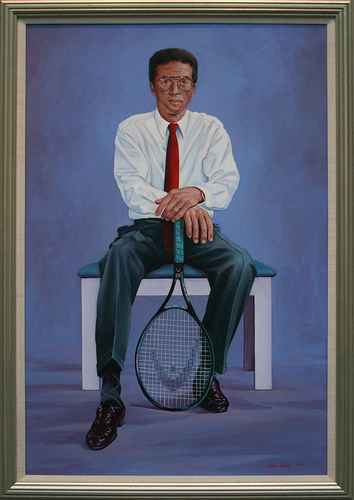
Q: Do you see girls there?
A: No, there are no girls.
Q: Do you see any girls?
A: No, there are no girls.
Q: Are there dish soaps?
A: No, there are no dish soaps.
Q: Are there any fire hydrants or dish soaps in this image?
A: No, there are no dish soaps or fire hydrants.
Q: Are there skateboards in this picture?
A: No, there are no skateboards.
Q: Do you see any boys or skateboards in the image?
A: No, there are no skateboards or boys.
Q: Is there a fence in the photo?
A: No, there are no fences.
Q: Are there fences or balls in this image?
A: No, there are no fences or balls.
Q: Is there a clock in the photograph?
A: No, there are no clocks.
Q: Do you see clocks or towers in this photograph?
A: No, there are no clocks or towers.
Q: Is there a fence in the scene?
A: No, there are no fences.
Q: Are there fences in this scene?
A: No, there are no fences.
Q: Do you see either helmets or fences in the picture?
A: No, there are no fences or helmets.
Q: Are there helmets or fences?
A: No, there are no fences or helmets.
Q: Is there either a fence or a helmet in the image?
A: No, there are no fences or helmets.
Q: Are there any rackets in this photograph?
A: Yes, there is a racket.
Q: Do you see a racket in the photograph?
A: Yes, there is a racket.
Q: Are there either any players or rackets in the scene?
A: Yes, there is a racket.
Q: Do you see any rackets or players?
A: Yes, there is a racket.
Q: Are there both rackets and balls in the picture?
A: No, there is a racket but no balls.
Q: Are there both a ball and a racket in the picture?
A: No, there is a racket but no balls.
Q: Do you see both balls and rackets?
A: No, there is a racket but no balls.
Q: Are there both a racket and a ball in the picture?
A: No, there is a racket but no balls.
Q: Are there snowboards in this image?
A: No, there are no snowboards.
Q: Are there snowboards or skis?
A: No, there are no snowboards or skis.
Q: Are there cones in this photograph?
A: No, there are no cones.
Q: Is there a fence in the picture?
A: No, there are no fences.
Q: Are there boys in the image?
A: No, there are no boys.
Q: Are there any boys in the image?
A: No, there are no boys.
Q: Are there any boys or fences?
A: No, there are no boys or fences.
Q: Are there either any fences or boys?
A: No, there are no boys or fences.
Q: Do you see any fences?
A: No, there are no fences.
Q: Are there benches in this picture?
A: Yes, there is a bench.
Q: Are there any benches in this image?
A: Yes, there is a bench.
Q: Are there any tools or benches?
A: Yes, there is a bench.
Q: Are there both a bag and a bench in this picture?
A: No, there is a bench but no bags.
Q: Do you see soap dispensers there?
A: No, there are no soap dispensers.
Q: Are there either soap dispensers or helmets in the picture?
A: No, there are no soap dispensers or helmets.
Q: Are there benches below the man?
A: Yes, there is a bench below the man.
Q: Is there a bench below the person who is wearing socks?
A: Yes, there is a bench below the man.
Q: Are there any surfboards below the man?
A: No, there is a bench below the man.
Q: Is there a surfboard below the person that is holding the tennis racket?
A: No, there is a bench below the man.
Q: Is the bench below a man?
A: Yes, the bench is below a man.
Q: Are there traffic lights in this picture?
A: No, there are no traffic lights.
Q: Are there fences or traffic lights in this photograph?
A: No, there are no traffic lights or fences.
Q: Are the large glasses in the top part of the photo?
A: Yes, the glasses are in the top of the image.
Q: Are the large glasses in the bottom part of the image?
A: No, the glasses are in the top of the image.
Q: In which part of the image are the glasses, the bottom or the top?
A: The glasses are in the top of the image.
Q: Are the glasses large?
A: Yes, the glasses are large.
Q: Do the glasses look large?
A: Yes, the glasses are large.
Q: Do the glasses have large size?
A: Yes, the glasses are large.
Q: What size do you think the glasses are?
A: The glasses are large.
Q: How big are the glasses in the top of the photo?
A: The glasses are large.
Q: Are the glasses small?
A: No, the glasses are large.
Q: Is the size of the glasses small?
A: No, the glasses are large.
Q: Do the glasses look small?
A: No, the glasses are large.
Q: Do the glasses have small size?
A: No, the glasses are large.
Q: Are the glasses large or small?
A: The glasses are large.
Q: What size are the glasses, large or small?
A: The glasses are large.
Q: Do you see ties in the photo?
A: Yes, there is a tie.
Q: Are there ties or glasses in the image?
A: Yes, there is a tie.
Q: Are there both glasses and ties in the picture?
A: Yes, there are both a tie and glasses.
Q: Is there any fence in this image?
A: No, there are no fences.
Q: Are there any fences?
A: No, there are no fences.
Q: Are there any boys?
A: No, there are no boys.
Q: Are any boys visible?
A: No, there are no boys.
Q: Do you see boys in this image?
A: No, there are no boys.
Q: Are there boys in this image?
A: No, there are no boys.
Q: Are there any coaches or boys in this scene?
A: No, there are no boys or coaches.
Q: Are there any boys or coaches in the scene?
A: No, there are no boys or coaches.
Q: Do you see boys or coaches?
A: No, there are no boys or coaches.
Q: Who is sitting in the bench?
A: The man is sitting in the bench.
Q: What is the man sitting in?
A: The man is sitting in the bench.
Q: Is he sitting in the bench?
A: Yes, the man is sitting in the bench.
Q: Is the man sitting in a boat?
A: No, the man is sitting in the bench.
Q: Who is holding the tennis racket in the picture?
A: The man is holding the tennis racket.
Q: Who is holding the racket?
A: The man is holding the tennis racket.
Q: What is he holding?
A: The man is holding the racket.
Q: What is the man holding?
A: The man is holding the racket.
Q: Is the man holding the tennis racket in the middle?
A: Yes, the man is holding the racket.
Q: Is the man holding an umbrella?
A: No, the man is holding the racket.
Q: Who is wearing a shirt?
A: The man is wearing a shirt.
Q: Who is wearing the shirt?
A: The man is wearing a shirt.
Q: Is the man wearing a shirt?
A: Yes, the man is wearing a shirt.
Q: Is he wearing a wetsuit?
A: No, the man is wearing a shirt.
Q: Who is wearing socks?
A: The man is wearing socks.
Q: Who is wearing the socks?
A: The man is wearing socks.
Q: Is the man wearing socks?
A: Yes, the man is wearing socks.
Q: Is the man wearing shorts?
A: No, the man is wearing socks.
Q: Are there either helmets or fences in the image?
A: No, there are no fences or helmets.